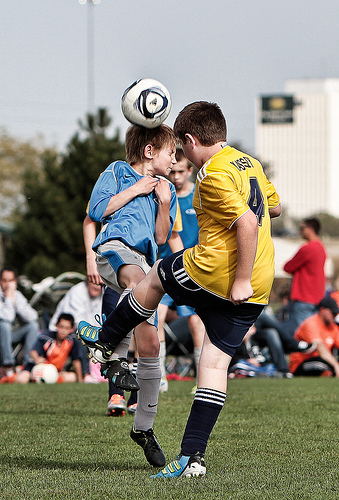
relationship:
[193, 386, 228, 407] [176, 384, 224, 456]
stripe on socks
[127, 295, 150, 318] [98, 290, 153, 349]
stripe on sock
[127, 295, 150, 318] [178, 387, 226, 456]
stripe on sock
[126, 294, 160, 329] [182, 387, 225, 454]
stripes on sock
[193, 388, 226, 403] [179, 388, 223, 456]
stripe on socks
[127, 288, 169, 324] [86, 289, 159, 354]
stripe on sock